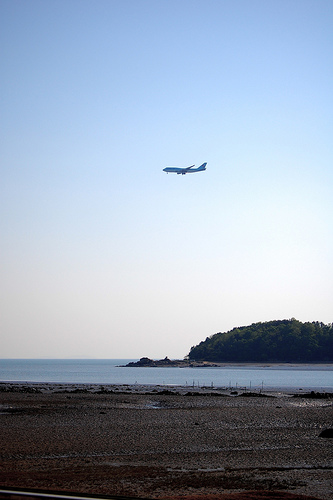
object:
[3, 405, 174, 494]
beach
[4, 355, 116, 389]
water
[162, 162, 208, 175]
airliner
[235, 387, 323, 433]
beach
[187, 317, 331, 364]
forest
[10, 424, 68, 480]
sand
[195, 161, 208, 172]
tail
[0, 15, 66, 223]
sky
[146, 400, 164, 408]
water puddle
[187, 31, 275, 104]
sky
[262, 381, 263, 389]
twig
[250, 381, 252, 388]
twig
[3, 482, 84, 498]
line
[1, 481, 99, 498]
surface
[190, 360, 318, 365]
land mass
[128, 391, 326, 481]
land mass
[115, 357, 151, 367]
rocks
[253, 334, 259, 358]
trees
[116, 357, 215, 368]
island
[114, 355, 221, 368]
land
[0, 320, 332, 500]
section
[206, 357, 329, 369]
shoreline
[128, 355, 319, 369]
beach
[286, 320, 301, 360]
trees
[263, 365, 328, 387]
water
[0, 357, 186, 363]
horizon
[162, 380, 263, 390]
fence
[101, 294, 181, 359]
sky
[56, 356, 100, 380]
water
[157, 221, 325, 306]
sky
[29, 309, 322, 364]
distance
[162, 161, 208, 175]
flight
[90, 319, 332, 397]
background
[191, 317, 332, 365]
mass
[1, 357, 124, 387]
ocean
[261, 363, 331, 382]
ocean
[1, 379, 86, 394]
sand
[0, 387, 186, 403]
grass